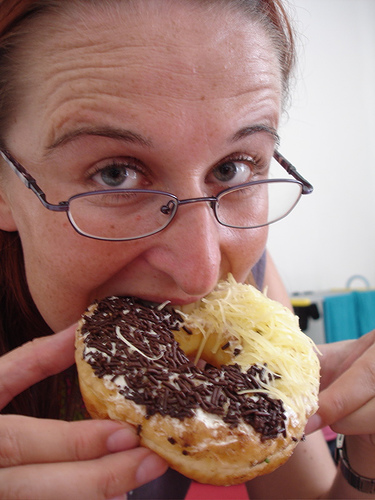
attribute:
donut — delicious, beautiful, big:
[78, 296, 321, 488]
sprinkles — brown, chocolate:
[102, 323, 172, 385]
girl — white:
[8, 1, 286, 315]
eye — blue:
[84, 158, 152, 193]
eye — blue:
[211, 156, 260, 187]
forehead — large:
[39, 9, 280, 116]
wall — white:
[293, 1, 374, 168]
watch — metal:
[335, 438, 374, 492]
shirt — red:
[190, 488, 250, 499]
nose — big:
[149, 176, 219, 292]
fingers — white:
[2, 412, 169, 499]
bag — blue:
[324, 293, 375, 331]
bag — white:
[293, 294, 320, 332]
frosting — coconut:
[234, 306, 294, 355]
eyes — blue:
[81, 158, 259, 186]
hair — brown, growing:
[234, 1, 291, 98]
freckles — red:
[178, 219, 201, 231]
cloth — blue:
[253, 264, 264, 289]